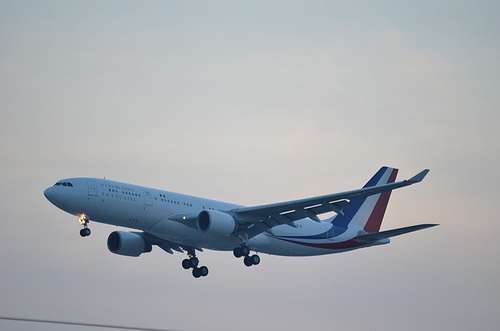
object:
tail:
[328, 165, 402, 232]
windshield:
[53, 178, 74, 187]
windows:
[153, 193, 194, 207]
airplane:
[44, 165, 442, 278]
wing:
[235, 167, 432, 221]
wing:
[120, 226, 204, 254]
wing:
[358, 221, 437, 242]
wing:
[325, 165, 400, 231]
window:
[55, 181, 73, 188]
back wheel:
[243, 254, 261, 267]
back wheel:
[231, 245, 248, 257]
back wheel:
[191, 265, 208, 278]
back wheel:
[180, 256, 200, 269]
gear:
[116, 212, 281, 281]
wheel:
[79, 227, 91, 238]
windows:
[108, 188, 142, 197]